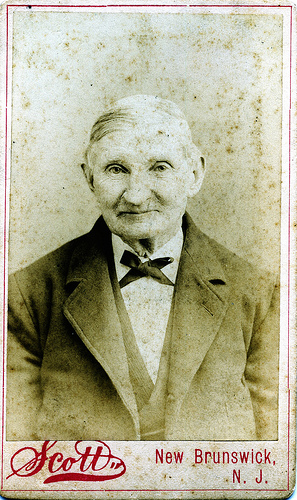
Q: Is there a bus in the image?
A: No, there are no buses.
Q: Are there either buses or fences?
A: No, there are no buses or fences.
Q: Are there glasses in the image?
A: No, there are no glasses.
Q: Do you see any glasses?
A: No, there are no glasses.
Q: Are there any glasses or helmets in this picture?
A: No, there are no glasses or helmets.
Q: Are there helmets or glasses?
A: No, there are no glasses or helmets.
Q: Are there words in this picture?
A: Yes, there are words.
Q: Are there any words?
A: Yes, there are words.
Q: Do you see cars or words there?
A: Yes, there are words.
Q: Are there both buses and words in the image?
A: No, there are words but no buses.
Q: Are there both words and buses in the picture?
A: No, there are words but no buses.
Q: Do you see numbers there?
A: No, there are no numbers.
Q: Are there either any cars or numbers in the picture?
A: No, there are no numbers or cars.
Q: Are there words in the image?
A: Yes, there are words.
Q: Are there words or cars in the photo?
A: Yes, there are words.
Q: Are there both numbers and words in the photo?
A: No, there are words but no numbers.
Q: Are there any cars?
A: No, there are no cars.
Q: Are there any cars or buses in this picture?
A: No, there are no cars or buses.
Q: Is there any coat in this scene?
A: Yes, there is a coat.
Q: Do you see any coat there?
A: Yes, there is a coat.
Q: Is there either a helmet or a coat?
A: Yes, there is a coat.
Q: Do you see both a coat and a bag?
A: No, there is a coat but no bags.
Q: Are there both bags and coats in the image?
A: No, there is a coat but no bags.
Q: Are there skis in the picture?
A: No, there are no skis.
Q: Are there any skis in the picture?
A: No, there are no skis.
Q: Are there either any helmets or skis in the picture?
A: No, there are no skis or helmets.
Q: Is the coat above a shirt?
A: Yes, the coat is above a shirt.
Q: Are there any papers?
A: No, there are no papers.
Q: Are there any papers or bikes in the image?
A: No, there are no papers or bikes.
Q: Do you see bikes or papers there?
A: No, there are no papers or bikes.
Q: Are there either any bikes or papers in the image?
A: No, there are no papers or bikes.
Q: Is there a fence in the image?
A: No, there are no fences.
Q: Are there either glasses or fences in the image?
A: No, there are no fences or glasses.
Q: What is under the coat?
A: The shirt is under the coat.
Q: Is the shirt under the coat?
A: Yes, the shirt is under the coat.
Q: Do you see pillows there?
A: No, there are no pillows.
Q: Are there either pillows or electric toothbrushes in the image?
A: No, there are no pillows or electric toothbrushes.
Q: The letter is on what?
A: The letter is on the sign.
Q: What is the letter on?
A: The letter is on the sign.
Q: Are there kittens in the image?
A: Yes, there is a kitten.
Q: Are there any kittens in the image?
A: Yes, there is a kitten.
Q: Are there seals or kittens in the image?
A: Yes, there is a kitten.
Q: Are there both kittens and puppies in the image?
A: No, there is a kitten but no puppies.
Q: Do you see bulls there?
A: No, there are no bulls.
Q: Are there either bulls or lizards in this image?
A: No, there are no bulls or lizards.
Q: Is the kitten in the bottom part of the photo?
A: Yes, the kitten is in the bottom of the image.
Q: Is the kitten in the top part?
A: No, the kitten is in the bottom of the image.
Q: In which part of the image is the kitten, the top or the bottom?
A: The kitten is in the bottom of the image.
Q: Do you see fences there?
A: No, there are no fences.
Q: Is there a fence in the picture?
A: No, there are no fences.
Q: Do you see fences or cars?
A: No, there are no fences or cars.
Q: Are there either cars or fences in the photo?
A: No, there are no fences or cars.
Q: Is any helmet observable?
A: No, there are no helmets.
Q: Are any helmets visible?
A: No, there are no helmets.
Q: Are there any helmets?
A: No, there are no helmets.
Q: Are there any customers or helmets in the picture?
A: No, there are no helmets or customers.